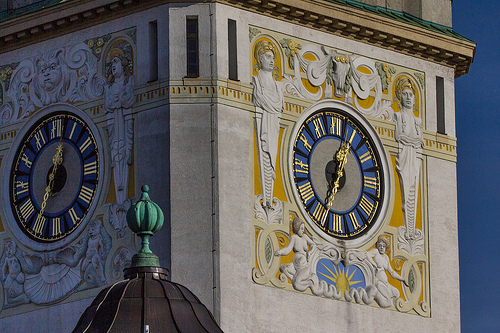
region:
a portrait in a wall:
[253, 35, 281, 210]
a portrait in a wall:
[396, 75, 421, 239]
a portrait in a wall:
[278, 210, 313, 292]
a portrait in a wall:
[369, 224, 398, 310]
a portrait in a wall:
[103, 44, 143, 204]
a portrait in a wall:
[73, 215, 103, 281]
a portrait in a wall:
[0, 234, 39, 314]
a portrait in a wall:
[18, 46, 88, 90]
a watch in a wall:
[277, 93, 396, 246]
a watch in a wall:
[11, 112, 102, 246]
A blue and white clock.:
[285, 99, 390, 249]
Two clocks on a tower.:
[1, 97, 393, 252]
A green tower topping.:
[123, 181, 165, 267]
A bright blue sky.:
[451, 0, 498, 332]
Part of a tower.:
[71, 181, 223, 331]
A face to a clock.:
[289, 106, 381, 237]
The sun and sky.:
[315, 257, 367, 299]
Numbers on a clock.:
[292, 111, 382, 239]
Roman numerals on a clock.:
[291, 110, 381, 239]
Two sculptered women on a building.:
[274, 218, 411, 310]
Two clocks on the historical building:
[2, 5, 499, 332]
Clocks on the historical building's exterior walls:
[7, 100, 393, 252]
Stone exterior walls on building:
[6, 7, 476, 330]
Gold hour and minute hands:
[320, 136, 358, 212]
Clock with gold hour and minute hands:
[286, 102, 389, 244]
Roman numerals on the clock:
[288, 102, 390, 248]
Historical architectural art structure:
[1, 3, 477, 331]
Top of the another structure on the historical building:
[66, 182, 222, 331]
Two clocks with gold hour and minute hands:
[2, 2, 475, 331]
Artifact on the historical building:
[246, 20, 430, 317]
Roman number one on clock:
[345, 122, 360, 145]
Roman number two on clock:
[356, 146, 376, 164]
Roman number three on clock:
[360, 171, 380, 187]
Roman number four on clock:
[355, 191, 375, 214]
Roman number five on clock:
[343, 207, 359, 228]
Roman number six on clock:
[327, 210, 340, 233]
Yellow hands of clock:
[315, 127, 351, 222]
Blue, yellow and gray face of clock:
[278, 98, 395, 251]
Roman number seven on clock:
[308, 193, 328, 228]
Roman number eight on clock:
[295, 179, 312, 204]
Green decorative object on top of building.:
[133, 175, 191, 330]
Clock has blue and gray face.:
[273, 85, 380, 277]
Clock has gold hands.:
[314, 132, 367, 262]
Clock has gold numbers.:
[292, 105, 368, 270]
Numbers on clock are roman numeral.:
[299, 101, 366, 240]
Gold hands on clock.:
[34, 127, 116, 269]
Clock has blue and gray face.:
[19, 115, 119, 282]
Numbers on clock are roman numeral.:
[23, 92, 128, 297]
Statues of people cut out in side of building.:
[239, 37, 477, 230]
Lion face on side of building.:
[15, 57, 104, 109]